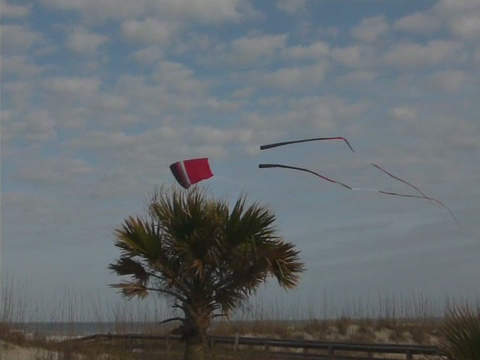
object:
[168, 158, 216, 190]
kite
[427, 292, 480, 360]
bush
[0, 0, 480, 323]
day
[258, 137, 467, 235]
tail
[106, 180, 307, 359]
tree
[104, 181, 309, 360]
fonds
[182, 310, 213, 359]
trunk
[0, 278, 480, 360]
weeds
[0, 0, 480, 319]
air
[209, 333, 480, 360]
rail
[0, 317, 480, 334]
shoreline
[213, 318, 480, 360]
dune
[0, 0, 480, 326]
sky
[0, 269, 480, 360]
grass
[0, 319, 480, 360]
ground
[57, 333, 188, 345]
post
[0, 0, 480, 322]
clouds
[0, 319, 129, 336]
water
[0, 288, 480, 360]
beach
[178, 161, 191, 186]
stripe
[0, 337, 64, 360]
sand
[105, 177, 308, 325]
leaves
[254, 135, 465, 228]
streamers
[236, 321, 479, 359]
pathway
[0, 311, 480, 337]
ocean